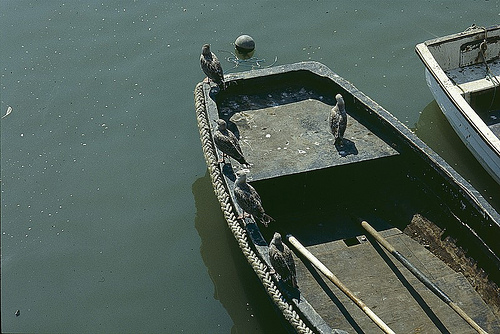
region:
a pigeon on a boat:
[296, 71, 392, 168]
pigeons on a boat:
[144, 18, 394, 283]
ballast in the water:
[230, 28, 260, 55]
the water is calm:
[47, 53, 159, 185]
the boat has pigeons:
[128, 11, 482, 323]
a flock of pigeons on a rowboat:
[144, 14, 458, 320]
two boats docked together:
[229, 8, 499, 215]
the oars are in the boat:
[291, 183, 441, 331]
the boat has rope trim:
[182, 209, 362, 331]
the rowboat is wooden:
[169, 22, 459, 305]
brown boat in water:
[171, 45, 421, 330]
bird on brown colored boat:
[194, 35, 228, 103]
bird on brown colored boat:
[217, 26, 258, 63]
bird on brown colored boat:
[321, 83, 352, 150]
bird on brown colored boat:
[244, 212, 299, 287]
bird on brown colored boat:
[221, 163, 263, 223]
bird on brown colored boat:
[197, 113, 258, 188]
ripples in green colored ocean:
[60, 188, 101, 223]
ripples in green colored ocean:
[65, 85, 105, 159]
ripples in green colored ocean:
[10, 196, 71, 223]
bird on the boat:
[316, 95, 361, 142]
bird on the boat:
[201, 48, 230, 85]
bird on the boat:
[211, 128, 252, 155]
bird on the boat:
[233, 165, 269, 225]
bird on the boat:
[268, 232, 300, 307]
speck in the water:
[127, 91, 146, 105]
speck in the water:
[24, 225, 45, 240]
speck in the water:
[21, 232, 31, 239]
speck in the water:
[15, 40, 33, 57]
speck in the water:
[356, 45, 378, 68]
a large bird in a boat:
[323, 88, 350, 143]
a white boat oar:
[285, 230, 395, 332]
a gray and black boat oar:
[356, 213, 493, 332]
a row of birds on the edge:
[211, 116, 304, 300]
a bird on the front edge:
[201, 42, 226, 86]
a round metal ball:
[235, 35, 255, 53]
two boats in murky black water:
[0, 0, 497, 331]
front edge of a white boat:
[410, 30, 499, 187]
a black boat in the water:
[195, 58, 497, 332]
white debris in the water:
[2, 104, 17, 117]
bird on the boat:
[208, 119, 246, 166]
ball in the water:
[234, 30, 264, 60]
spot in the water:
[97, 114, 115, 139]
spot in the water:
[56, 203, 76, 220]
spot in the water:
[13, 126, 28, 148]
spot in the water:
[27, 63, 46, 78]